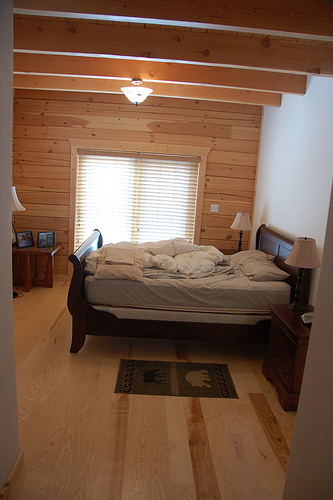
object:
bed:
[69, 221, 310, 353]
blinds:
[76, 150, 206, 249]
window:
[72, 146, 205, 261]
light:
[121, 79, 152, 106]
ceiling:
[13, 0, 333, 125]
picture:
[16, 226, 34, 249]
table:
[12, 241, 62, 289]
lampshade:
[228, 206, 250, 253]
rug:
[114, 360, 244, 405]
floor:
[13, 271, 302, 499]